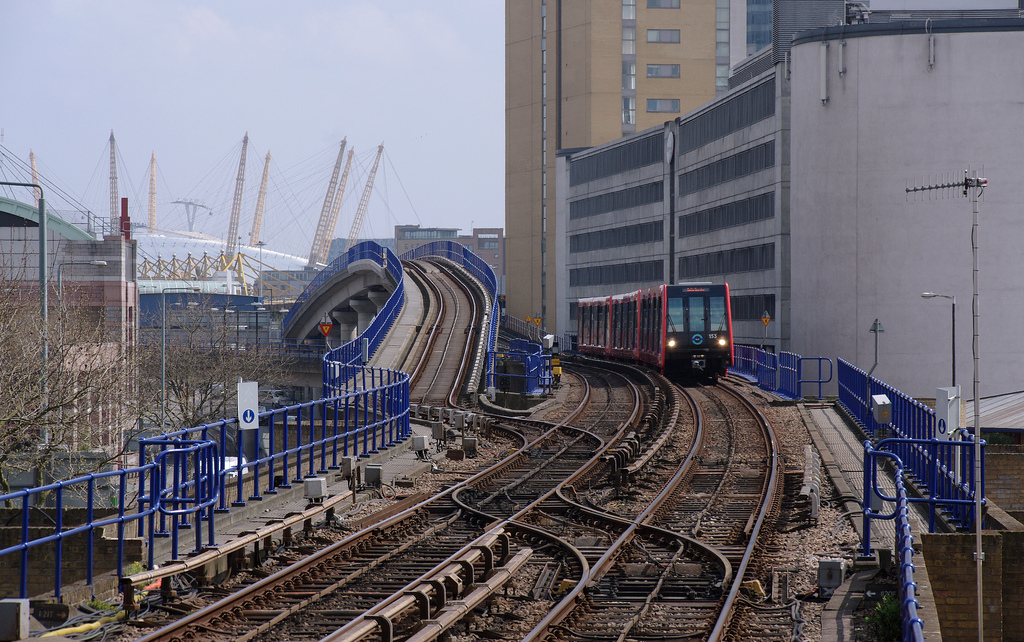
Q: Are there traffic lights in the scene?
A: No, there are no traffic lights.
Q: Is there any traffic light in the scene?
A: No, there are no traffic lights.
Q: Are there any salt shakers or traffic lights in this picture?
A: No, there are no traffic lights or salt shakers.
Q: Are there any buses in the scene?
A: No, there are no buses.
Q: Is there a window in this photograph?
A: Yes, there is a window.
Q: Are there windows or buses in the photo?
A: Yes, there is a window.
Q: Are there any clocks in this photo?
A: No, there are no clocks.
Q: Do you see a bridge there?
A: Yes, there is a bridge.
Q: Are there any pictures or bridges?
A: Yes, there is a bridge.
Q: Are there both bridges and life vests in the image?
A: No, there is a bridge but no life jackets.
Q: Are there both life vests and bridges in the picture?
A: No, there is a bridge but no life jackets.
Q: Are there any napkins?
A: No, there are no napkins.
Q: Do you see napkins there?
A: No, there are no napkins.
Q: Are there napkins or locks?
A: No, there are no napkins or locks.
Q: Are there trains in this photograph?
A: Yes, there is a train.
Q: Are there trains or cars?
A: Yes, there is a train.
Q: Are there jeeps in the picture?
A: No, there are no jeeps.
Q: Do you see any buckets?
A: No, there are no buckets.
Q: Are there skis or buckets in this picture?
A: No, there are no buckets or skis.